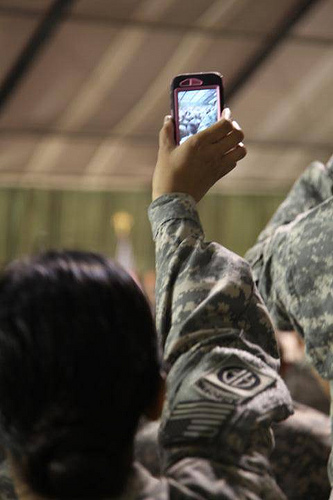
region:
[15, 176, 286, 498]
A woman in army uniform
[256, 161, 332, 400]
A person in army uniform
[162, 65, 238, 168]
a cell phone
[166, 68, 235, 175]
A pink and black case on the cell phone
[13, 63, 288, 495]
a woman holding up her cell phone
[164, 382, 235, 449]
an american flag on the army uniform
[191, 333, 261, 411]
a patch on the army uniform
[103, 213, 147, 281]
A blurry american flag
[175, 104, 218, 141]
An image of several people on the cell phone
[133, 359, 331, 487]
A person in army uniform in front of the woman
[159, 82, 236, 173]
person holds black phone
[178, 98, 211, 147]
image on phone screen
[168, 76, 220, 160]
cell phone in air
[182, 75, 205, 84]
pink speaker on phone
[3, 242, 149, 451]
woman has dark hair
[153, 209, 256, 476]
woman has camouflage outfit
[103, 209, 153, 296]
flag is in distance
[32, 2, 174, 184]
ceiling is light colored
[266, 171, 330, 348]
person next to woman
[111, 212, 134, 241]
yellow tip on flag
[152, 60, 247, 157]
cellphone with a picture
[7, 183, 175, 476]
woman with dark brown hair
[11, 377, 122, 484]
hair wrapped in a bun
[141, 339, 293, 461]
patches on a sleeve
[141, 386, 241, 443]
patch of the american flag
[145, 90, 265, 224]
hand holding a cellphone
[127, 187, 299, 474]
camoflauged arm sleeve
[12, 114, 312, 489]
woman wearing a military uniform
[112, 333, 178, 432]
a woman's ear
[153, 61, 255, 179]
black and pink cellphone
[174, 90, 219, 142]
Display on a cell phone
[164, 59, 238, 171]
Cell phone being used as a camera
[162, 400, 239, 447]
American flag patch on a uniform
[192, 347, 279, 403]
Patch on a uniform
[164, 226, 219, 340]
Camouflage fatigues worn by soldier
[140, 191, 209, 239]
Cuffs on his sleeve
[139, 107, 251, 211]
Hand holding a cell phone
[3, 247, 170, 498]
Back of soldiers head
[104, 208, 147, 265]
Blurry flagpole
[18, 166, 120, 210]
Seam between the wall and ceiling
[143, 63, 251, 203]
person holding a phone.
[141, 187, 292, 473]
person wearing camouflage.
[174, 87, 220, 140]
the screen is on.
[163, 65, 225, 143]
the phone is black and pink.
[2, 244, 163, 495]
the person has black hair.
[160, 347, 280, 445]
patches on person's sleeve.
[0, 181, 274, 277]
the wall is green.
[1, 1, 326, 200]
the ceiling is white.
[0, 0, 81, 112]
the pole is black.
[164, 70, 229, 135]
one phone is visible.